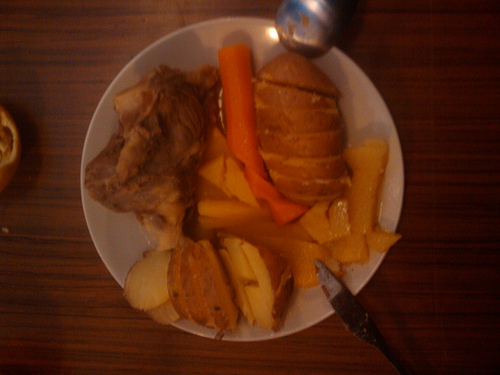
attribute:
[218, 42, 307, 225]
carrot — cooked, whole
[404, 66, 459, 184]
table — wooden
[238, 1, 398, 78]
spoon — scooping 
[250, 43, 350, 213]
potato — brown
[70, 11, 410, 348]
plate — serving, dinner, plastic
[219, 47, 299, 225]
carrot — orange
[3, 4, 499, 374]
table — brown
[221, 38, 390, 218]
bread — sliced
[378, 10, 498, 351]
table — brown, wooden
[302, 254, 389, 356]
knife — gray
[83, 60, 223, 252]
serving — meat